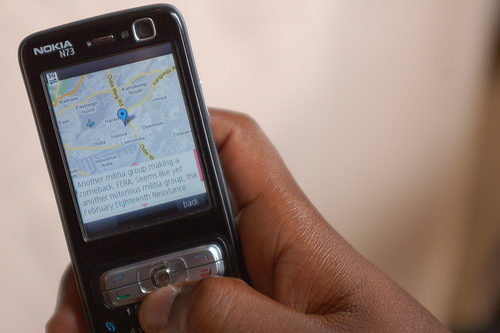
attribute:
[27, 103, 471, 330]
person — brown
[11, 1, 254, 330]
phone — black, nokia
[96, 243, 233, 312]
keys — silver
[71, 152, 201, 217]
words — describing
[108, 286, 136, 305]
button — green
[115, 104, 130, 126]
dot — blue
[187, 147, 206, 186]
line — red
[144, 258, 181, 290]
button — silver